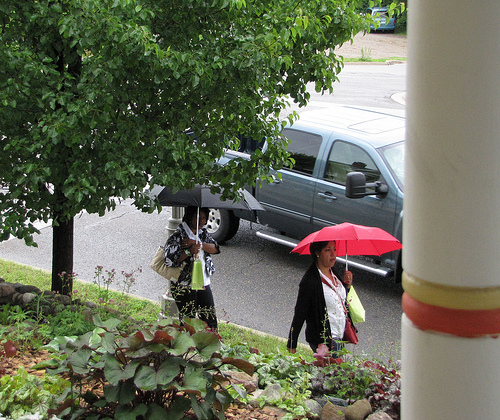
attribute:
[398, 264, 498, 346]
stripe — red, yellow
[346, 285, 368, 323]
bag — lime green, small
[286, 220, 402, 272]
umbrella — red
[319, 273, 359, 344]
purse — Red 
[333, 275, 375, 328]
bag — green 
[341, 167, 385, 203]
mirror — side-view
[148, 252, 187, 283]
bag — white , tan 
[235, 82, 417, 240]
car — blue 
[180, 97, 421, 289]
truck — parked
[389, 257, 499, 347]
ring — yellow , red 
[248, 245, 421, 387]
woman — walking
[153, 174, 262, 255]
umbrella — black 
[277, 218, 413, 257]
umbrella — red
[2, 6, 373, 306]
tree — green 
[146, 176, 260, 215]
umbrella — black 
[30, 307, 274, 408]
foliage — above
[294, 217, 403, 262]
umbrella — red